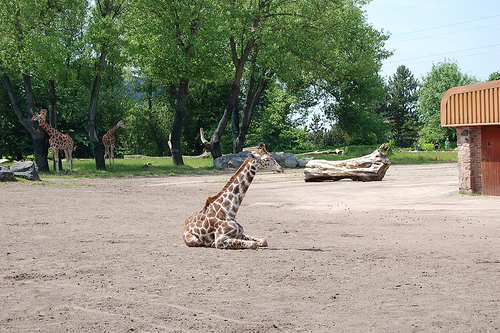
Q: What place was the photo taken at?
A: It was taken at the park.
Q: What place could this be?
A: It is a park.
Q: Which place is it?
A: It is a park.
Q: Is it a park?
A: Yes, it is a park.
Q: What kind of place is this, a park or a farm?
A: It is a park.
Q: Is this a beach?
A: No, it is a park.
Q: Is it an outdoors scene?
A: Yes, it is outdoors.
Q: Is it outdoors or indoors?
A: It is outdoors.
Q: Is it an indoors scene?
A: No, it is outdoors.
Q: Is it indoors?
A: No, it is outdoors.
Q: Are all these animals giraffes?
A: Yes, all the animals are giraffes.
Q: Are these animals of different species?
A: No, all the animals are giraffes.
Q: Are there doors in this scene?
A: Yes, there is a door.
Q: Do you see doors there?
A: Yes, there is a door.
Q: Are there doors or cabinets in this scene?
A: Yes, there is a door.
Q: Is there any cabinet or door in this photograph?
A: Yes, there is a door.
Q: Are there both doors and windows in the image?
A: No, there is a door but no windows.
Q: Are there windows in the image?
A: No, there are no windows.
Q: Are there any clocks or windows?
A: No, there are no windows or clocks.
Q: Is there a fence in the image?
A: No, there are no fences.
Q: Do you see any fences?
A: No, there are no fences.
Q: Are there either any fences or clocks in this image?
A: No, there are no fences or clocks.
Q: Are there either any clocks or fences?
A: No, there are no fences or clocks.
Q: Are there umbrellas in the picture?
A: No, there are no umbrellas.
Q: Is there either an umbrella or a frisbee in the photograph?
A: No, there are no umbrellas or frisbees.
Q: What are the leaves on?
A: The leaves are on the trees.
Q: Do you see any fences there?
A: No, there are no fences.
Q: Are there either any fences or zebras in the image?
A: No, there are no fences or zebras.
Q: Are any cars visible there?
A: No, there are no cars.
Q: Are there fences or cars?
A: No, there are no cars or fences.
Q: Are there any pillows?
A: No, there are no pillows.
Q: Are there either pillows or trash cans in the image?
A: No, there are no pillows or trash cans.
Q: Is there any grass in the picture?
A: Yes, there is grass.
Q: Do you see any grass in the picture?
A: Yes, there is grass.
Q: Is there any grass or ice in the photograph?
A: Yes, there is grass.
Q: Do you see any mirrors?
A: No, there are no mirrors.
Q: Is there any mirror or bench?
A: No, there are no mirrors or benches.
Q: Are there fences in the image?
A: No, there are no fences.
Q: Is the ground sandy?
A: Yes, the ground is sandy.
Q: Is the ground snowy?
A: No, the ground is sandy.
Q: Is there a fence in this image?
A: No, there are no fences.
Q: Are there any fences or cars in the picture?
A: No, there are no fences or cars.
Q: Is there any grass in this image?
A: Yes, there is grass.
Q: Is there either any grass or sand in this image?
A: Yes, there is grass.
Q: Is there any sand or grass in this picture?
A: Yes, there is grass.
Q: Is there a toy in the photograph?
A: No, there are no toys.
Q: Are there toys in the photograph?
A: No, there are no toys.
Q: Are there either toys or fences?
A: No, there are no toys or fences.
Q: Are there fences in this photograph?
A: No, there are no fences.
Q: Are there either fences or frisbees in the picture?
A: No, there are no fences or frisbees.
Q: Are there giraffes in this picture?
A: Yes, there is a giraffe.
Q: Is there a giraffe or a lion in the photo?
A: Yes, there is a giraffe.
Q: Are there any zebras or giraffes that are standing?
A: Yes, the giraffe is standing.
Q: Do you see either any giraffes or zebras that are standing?
A: Yes, the giraffe is standing.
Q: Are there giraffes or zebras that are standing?
A: Yes, the giraffe is standing.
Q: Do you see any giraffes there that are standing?
A: Yes, there is a giraffe that is standing.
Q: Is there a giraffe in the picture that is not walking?
A: Yes, there is a giraffe that is standing.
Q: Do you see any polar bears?
A: No, there are no polar bears.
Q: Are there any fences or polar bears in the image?
A: No, there are no polar bears or fences.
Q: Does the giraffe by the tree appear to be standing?
A: Yes, the giraffe is standing.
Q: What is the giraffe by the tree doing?
A: The giraffe is standing.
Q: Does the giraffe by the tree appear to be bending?
A: No, the giraffe is standing.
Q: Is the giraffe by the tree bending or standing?
A: The giraffe is standing.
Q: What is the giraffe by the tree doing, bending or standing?
A: The giraffe is standing.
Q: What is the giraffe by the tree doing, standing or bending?
A: The giraffe is standing.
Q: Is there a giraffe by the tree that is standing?
A: Yes, there is a giraffe by the tree.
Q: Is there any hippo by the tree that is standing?
A: No, there is a giraffe by the tree.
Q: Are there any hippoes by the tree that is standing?
A: No, there is a giraffe by the tree.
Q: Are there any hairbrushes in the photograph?
A: No, there are no hairbrushes.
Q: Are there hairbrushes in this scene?
A: No, there are no hairbrushes.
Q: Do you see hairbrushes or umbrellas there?
A: No, there are no hairbrushes or umbrellas.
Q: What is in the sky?
A: The power lines are in the sky.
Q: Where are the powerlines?
A: The powerlines are in the sky.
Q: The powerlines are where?
A: The powerlines are in the sky.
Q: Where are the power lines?
A: The powerlines are in the sky.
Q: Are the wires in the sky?
A: Yes, the wires are in the sky.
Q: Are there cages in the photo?
A: No, there are no cages.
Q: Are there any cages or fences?
A: No, there are no cages or fences.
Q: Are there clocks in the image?
A: No, there are no clocks.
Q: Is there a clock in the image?
A: No, there are no clocks.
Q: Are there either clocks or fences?
A: No, there are no clocks or fences.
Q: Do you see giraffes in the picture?
A: Yes, there are giraffes.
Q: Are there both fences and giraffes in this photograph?
A: No, there are giraffes but no fences.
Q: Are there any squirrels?
A: No, there are no squirrels.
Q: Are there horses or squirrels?
A: No, there are no squirrels or horses.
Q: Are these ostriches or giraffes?
A: These are giraffes.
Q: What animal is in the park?
A: The giraffes are in the park.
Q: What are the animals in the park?
A: The animals are giraffes.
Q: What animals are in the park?
A: The animals are giraffes.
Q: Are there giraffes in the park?
A: Yes, there are giraffes in the park.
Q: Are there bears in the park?
A: No, there are giraffes in the park.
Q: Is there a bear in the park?
A: No, there are giraffes in the park.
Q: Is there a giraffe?
A: Yes, there are giraffes.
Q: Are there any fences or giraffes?
A: Yes, there are giraffes.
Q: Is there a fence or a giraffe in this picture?
A: Yes, there are giraffes.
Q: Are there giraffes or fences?
A: Yes, there are giraffes.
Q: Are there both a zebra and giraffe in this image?
A: No, there are giraffes but no zebras.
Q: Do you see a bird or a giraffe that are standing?
A: Yes, the giraffes are standing.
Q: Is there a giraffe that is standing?
A: Yes, there are giraffes that are standing.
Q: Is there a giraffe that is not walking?
A: Yes, there are giraffes that are standing.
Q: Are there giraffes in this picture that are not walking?
A: Yes, there are giraffes that are standing.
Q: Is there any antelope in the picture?
A: No, there are no antelopes.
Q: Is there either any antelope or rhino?
A: No, there are no antelopes or rhinos.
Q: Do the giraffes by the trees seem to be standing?
A: Yes, the giraffes are standing.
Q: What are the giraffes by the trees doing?
A: The giraffes are standing.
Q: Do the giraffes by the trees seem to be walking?
A: No, the giraffes are standing.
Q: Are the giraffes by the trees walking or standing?
A: The giraffes are standing.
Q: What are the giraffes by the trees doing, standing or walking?
A: The giraffes are standing.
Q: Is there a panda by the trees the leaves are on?
A: No, there are giraffes by the trees.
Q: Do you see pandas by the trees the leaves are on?
A: No, there are giraffes by the trees.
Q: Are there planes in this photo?
A: No, there are no planes.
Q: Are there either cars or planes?
A: No, there are no planes or cars.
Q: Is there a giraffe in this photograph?
A: Yes, there is a giraffe.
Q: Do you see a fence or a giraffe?
A: Yes, there is a giraffe.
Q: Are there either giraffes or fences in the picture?
A: Yes, there is a giraffe.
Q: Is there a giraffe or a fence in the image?
A: Yes, there is a giraffe.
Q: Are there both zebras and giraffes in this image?
A: No, there is a giraffe but no zebras.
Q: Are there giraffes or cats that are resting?
A: Yes, the giraffe is resting.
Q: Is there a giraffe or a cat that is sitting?
A: Yes, the giraffe is sitting.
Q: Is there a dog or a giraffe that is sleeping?
A: Yes, the giraffe is sleeping.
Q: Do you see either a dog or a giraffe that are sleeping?
A: Yes, the giraffe is sleeping.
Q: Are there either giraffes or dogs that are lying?
A: Yes, the giraffe is lying.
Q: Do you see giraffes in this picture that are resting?
A: Yes, there is a giraffe that is resting.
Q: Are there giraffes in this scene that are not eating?
A: Yes, there is a giraffe that is resting.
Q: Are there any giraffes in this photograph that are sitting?
A: Yes, there is a giraffe that is sitting.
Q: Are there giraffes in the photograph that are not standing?
A: Yes, there is a giraffe that is sitting.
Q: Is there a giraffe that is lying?
A: Yes, there is a giraffe that is lying.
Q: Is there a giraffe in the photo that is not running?
A: Yes, there is a giraffe that is lying.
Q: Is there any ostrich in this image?
A: No, there are no ostriches.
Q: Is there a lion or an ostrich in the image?
A: No, there are no ostriches or lions.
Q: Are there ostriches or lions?
A: No, there are no ostriches or lions.